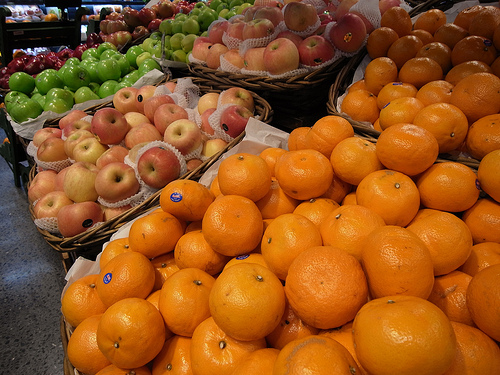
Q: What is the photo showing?
A: It is showing a display.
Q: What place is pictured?
A: It is a display.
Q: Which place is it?
A: It is a display.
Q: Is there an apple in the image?
A: Yes, there is an apple.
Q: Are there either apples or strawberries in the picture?
A: Yes, there is an apple.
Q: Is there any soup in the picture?
A: No, there is no soup.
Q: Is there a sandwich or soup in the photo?
A: No, there are no soup or sandwiches.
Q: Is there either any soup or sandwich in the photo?
A: No, there are no soup or sandwiches.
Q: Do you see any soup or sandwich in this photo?
A: No, there are no soup or sandwiches.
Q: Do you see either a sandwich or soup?
A: No, there are no soup or sandwiches.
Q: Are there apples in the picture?
A: Yes, there is an apple.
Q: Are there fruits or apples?
A: Yes, there is an apple.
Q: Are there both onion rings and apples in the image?
A: No, there is an apple but no onion rings.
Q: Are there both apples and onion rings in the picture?
A: No, there is an apple but no onion rings.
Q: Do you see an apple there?
A: Yes, there is an apple.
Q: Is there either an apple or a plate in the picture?
A: Yes, there is an apple.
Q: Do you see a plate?
A: No, there are no plates.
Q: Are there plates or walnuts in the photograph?
A: No, there are no plates or walnuts.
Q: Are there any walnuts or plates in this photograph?
A: No, there are no plates or walnuts.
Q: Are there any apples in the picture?
A: Yes, there is an apple.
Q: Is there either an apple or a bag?
A: Yes, there is an apple.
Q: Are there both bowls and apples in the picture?
A: No, there is an apple but no bowls.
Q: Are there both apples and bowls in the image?
A: No, there is an apple but no bowls.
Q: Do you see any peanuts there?
A: No, there are no peanuts.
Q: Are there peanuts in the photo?
A: No, there are no peanuts.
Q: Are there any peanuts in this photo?
A: No, there are no peanuts.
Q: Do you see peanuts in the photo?
A: No, there are no peanuts.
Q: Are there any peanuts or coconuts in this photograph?
A: No, there are no peanuts or coconuts.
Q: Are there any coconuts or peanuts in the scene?
A: No, there are no peanuts or coconuts.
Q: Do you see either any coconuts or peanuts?
A: No, there are no peanuts or coconuts.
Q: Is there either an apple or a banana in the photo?
A: Yes, there are apples.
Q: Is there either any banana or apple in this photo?
A: Yes, there are apples.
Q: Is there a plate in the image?
A: No, there are no plates.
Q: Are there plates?
A: No, there are no plates.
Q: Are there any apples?
A: Yes, there are apples.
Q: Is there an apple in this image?
A: Yes, there are apples.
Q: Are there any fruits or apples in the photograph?
A: Yes, there are apples.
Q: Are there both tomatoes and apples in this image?
A: No, there are apples but no tomatoes.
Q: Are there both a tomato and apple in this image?
A: No, there are apples but no tomatoes.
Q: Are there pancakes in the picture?
A: No, there are no pancakes.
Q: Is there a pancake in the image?
A: No, there are no pancakes.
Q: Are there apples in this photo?
A: Yes, there are apples.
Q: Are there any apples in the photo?
A: Yes, there are apples.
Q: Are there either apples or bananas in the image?
A: Yes, there are apples.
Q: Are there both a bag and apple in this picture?
A: No, there are apples but no bags.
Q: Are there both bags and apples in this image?
A: No, there are apples but no bags.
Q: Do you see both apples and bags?
A: No, there are apples but no bags.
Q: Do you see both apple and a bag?
A: No, there are apples but no bags.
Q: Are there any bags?
A: No, there are no bags.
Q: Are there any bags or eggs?
A: No, there are no bags or eggs.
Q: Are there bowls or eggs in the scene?
A: No, there are no bowls or eggs.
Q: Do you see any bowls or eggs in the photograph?
A: No, there are no bowls or eggs.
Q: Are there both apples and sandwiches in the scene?
A: No, there is an apple but no sandwiches.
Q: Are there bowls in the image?
A: No, there are no bowls.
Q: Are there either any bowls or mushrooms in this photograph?
A: No, there are no bowls or mushrooms.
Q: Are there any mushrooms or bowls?
A: No, there are no bowls or mushrooms.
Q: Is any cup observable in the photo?
A: Yes, there is a cup.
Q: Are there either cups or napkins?
A: Yes, there is a cup.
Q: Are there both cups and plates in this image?
A: No, there is a cup but no plates.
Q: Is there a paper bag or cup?
A: Yes, there is a paper cup.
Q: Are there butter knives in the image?
A: No, there are no butter knives.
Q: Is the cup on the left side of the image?
A: Yes, the cup is on the left of the image.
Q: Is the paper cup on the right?
A: No, the cup is on the left of the image.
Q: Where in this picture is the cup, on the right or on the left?
A: The cup is on the left of the image.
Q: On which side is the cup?
A: The cup is on the left of the image.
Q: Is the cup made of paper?
A: Yes, the cup is made of paper.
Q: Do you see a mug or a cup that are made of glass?
A: No, there is a cup but it is made of paper.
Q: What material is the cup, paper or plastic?
A: The cup is made of paper.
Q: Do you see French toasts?
A: No, there are no French toasts.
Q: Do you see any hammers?
A: No, there are no hammers.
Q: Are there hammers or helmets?
A: No, there are no hammers or helmets.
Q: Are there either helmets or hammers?
A: No, there are no hammers or helmets.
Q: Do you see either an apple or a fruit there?
A: Yes, there are apples.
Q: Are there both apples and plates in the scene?
A: No, there are apples but no plates.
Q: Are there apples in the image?
A: Yes, there are apples.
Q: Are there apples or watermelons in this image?
A: Yes, there are apples.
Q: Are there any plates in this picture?
A: No, there are no plates.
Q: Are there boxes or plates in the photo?
A: No, there are no plates or boxes.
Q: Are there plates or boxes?
A: No, there are no plates or boxes.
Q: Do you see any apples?
A: Yes, there are apples.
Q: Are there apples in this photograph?
A: Yes, there are apples.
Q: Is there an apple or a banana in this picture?
A: Yes, there are apples.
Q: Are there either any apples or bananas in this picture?
A: Yes, there are apples.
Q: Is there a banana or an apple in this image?
A: Yes, there are apples.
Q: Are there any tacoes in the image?
A: No, there are no tacoes.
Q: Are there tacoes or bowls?
A: No, there are no tacoes or bowls.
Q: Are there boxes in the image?
A: No, there are no boxes.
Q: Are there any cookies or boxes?
A: No, there are no boxes or cookies.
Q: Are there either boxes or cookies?
A: No, there are no boxes or cookies.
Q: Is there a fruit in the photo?
A: Yes, there is a fruit.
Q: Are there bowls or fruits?
A: Yes, there is a fruit.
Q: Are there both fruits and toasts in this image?
A: No, there is a fruit but no toasts.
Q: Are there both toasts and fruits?
A: No, there is a fruit but no toasts.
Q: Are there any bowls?
A: No, there are no bowls.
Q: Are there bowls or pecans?
A: No, there are no bowls or pecans.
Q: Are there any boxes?
A: No, there are no boxes.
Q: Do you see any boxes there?
A: No, there are no boxes.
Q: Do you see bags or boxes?
A: No, there are no boxes or bags.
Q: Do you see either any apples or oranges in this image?
A: Yes, there are oranges.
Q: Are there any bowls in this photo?
A: No, there are no bowls.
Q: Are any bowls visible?
A: No, there are no bowls.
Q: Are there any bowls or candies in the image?
A: No, there are no bowls or candies.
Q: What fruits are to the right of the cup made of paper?
A: The fruits are oranges.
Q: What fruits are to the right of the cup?
A: The fruits are oranges.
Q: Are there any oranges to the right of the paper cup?
A: Yes, there are oranges to the right of the cup.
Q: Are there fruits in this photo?
A: Yes, there is a fruit.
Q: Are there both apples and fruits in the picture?
A: Yes, there are both a fruit and an apple.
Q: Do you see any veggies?
A: No, there are no veggies.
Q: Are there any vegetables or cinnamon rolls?
A: No, there are no vegetables or cinnamon rolls.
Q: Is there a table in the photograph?
A: Yes, there is a table.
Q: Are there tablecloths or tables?
A: Yes, there is a table.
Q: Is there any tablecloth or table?
A: Yes, there is a table.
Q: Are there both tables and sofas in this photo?
A: No, there is a table but no sofas.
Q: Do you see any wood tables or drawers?
A: Yes, there is a wood table.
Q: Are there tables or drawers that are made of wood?
A: Yes, the table is made of wood.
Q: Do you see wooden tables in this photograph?
A: Yes, there is a wood table.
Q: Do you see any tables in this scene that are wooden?
A: Yes, there is a table that is wooden.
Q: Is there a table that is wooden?
A: Yes, there is a table that is wooden.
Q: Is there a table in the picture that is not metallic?
A: Yes, there is a wooden table.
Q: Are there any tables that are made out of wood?
A: Yes, there is a table that is made of wood.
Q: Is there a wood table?
A: Yes, there is a table that is made of wood.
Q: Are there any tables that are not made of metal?
A: Yes, there is a table that is made of wood.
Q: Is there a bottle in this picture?
A: No, there are no bottles.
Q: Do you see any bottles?
A: No, there are no bottles.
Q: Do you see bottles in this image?
A: No, there are no bottles.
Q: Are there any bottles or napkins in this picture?
A: No, there are no bottles or napkins.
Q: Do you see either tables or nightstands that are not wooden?
A: No, there is a table but it is wooden.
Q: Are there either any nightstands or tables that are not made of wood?
A: No, there is a table but it is made of wood.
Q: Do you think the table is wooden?
A: Yes, the table is wooden.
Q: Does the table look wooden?
A: Yes, the table is wooden.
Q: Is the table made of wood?
A: Yes, the table is made of wood.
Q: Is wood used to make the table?
A: Yes, the table is made of wood.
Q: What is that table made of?
A: The table is made of wood.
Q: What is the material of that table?
A: The table is made of wood.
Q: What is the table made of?
A: The table is made of wood.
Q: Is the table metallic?
A: No, the table is wooden.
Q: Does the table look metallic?
A: No, the table is wooden.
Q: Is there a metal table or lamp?
A: No, there is a table but it is wooden.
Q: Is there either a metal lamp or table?
A: No, there is a table but it is wooden.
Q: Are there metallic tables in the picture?
A: No, there is a table but it is wooden.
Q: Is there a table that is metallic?
A: No, there is a table but it is wooden.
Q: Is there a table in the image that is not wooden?
A: No, there is a table but it is wooden.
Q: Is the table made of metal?
A: No, the table is made of wood.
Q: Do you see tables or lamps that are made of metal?
A: No, there is a table but it is made of wood.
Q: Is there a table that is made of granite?
A: No, there is a table but it is made of wood.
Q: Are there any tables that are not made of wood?
A: No, there is a table but it is made of wood.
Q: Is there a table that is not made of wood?
A: No, there is a table but it is made of wood.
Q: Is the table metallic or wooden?
A: The table is wooden.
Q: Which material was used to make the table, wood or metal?
A: The table is made of wood.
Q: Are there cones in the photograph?
A: No, there are no cones.